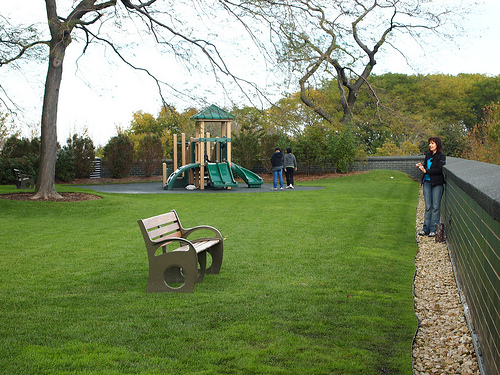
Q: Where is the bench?
A: In the park.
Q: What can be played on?
A: The play house.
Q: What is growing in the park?
A: Tree.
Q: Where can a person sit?
A: Bench.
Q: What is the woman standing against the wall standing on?
A: Rock.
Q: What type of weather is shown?
A: Clear.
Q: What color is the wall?
A: Gray.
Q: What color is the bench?
A: Tan.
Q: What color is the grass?
A: Green.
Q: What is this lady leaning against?
A: A wall.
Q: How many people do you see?
A: 3.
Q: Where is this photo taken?
A: Park.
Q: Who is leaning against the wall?
A: A lady.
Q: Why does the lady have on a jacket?
A: Cool outside.